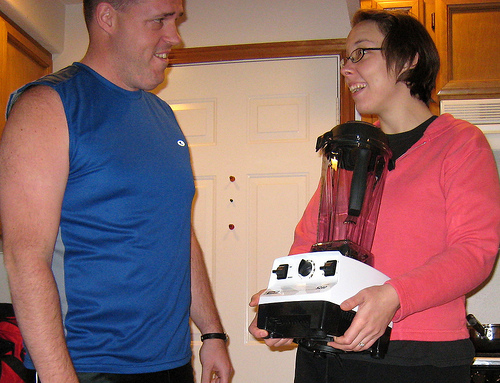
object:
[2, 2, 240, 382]
man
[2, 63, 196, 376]
shirt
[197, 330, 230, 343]
watch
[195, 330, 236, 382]
left hand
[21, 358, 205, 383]
pants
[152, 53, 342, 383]
door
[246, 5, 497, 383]
woman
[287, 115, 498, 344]
sweater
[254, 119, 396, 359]
blender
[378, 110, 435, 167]
shirt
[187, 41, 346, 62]
frame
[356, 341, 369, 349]
ring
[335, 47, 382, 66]
glasses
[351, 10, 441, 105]
hair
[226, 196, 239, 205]
peep hole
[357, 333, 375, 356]
finger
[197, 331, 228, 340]
wrist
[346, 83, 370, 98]
open mouth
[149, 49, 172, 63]
open mouth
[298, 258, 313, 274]
knob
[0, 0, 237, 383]
people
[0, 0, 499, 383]
in kitchen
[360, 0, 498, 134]
cabinets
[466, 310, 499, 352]
pot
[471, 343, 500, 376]
stove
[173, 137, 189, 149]
logo